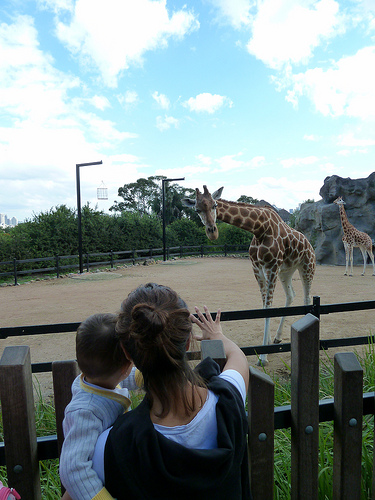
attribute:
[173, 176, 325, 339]
giraffe — tall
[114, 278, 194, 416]
hair — dark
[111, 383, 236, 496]
sweater — black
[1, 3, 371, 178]
sky — blue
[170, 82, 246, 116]
cloud — white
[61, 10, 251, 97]
clouds — white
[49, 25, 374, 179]
sky — blue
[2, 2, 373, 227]
sky — blue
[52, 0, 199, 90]
cloud — white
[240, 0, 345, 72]
cloud — white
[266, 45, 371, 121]
cloud — white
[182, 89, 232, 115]
cloud — white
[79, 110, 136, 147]
cloud — white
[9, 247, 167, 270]
fence — black, long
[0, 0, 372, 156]
sky — white, blue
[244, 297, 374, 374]
railing — metal, black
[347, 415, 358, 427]
bolts — black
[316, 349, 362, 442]
grass — green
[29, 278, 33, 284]
rock — grey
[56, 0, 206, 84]
cloud — white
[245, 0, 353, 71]
cloud — white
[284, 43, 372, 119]
cloud — white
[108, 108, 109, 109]
cloud — white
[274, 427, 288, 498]
grass — green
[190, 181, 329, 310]
giraffe — brown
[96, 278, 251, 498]
lady — holding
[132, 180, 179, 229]
tree — green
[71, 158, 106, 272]
pole — metal, black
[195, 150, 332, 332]
giraffe — white, brown, tall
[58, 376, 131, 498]
sweater — white, yellow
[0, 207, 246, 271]
trees — green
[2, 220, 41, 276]
section — long